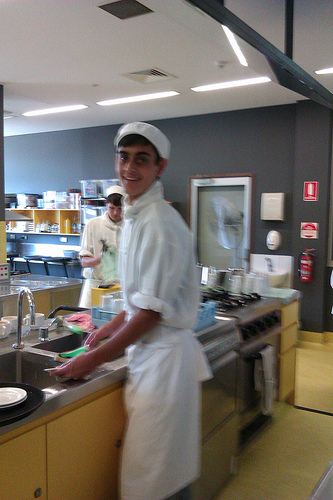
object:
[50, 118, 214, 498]
man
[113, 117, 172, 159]
hat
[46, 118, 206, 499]
boy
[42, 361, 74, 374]
dishes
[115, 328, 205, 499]
apron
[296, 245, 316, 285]
fire extinguisher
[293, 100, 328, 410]
wall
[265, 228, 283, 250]
dispenser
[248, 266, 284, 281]
sink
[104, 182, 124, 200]
hat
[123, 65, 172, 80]
air vent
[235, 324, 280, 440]
door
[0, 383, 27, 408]
plates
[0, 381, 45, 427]
tray